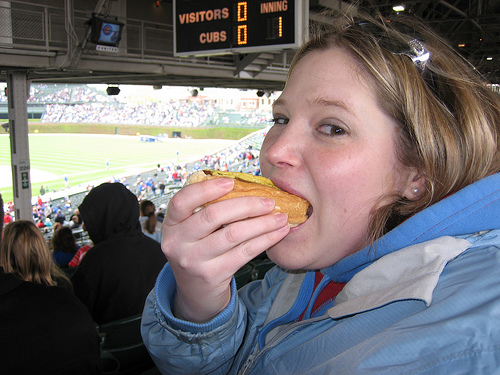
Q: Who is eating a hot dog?
A: A woman.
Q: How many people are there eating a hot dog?
A: One.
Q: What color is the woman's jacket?
A: Blue and white.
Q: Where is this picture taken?
A: At a baseball game.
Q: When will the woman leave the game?
A: After she finishes watching the game.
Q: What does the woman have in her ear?
A: An earring.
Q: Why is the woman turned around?
A: She is looking at the camera.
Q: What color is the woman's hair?
A: Brown.